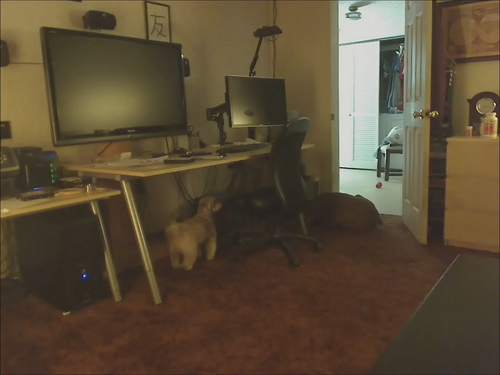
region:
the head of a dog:
[199, 187, 233, 217]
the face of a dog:
[194, 190, 234, 222]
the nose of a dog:
[214, 193, 231, 213]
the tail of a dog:
[163, 220, 187, 248]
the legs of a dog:
[161, 242, 198, 277]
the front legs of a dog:
[194, 225, 241, 267]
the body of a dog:
[168, 187, 220, 267]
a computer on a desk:
[205, 47, 314, 169]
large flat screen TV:
[46, 28, 190, 139]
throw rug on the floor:
[362, 256, 499, 374]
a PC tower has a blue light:
[15, 221, 107, 305]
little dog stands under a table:
[170, 181, 223, 273]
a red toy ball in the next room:
[373, 181, 385, 191]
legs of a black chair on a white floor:
[378, 141, 403, 183]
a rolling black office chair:
[231, 116, 321, 266]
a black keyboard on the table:
[212, 137, 264, 162]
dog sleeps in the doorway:
[310, 188, 385, 237]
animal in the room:
[145, 183, 237, 273]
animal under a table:
[136, 169, 256, 294]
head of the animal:
[191, 188, 231, 227]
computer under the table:
[6, 204, 115, 319]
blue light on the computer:
[63, 254, 100, 296]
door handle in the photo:
[394, 77, 459, 145]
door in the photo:
[317, 2, 491, 239]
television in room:
[17, 28, 230, 184]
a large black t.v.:
[33, 18, 196, 148]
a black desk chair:
[187, 113, 332, 275]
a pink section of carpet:
[0, 199, 433, 371]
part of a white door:
[336, 41, 383, 173]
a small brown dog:
[159, 190, 228, 272]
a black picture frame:
[140, 0, 180, 43]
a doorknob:
[410, 105, 426, 122]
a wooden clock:
[466, 90, 498, 124]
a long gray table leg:
[119, 180, 169, 307]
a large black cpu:
[8, 203, 103, 313]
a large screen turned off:
[38, 20, 190, 145]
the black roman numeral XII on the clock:
[226, 71, 290, 128]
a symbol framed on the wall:
[143, 1, 172, 41]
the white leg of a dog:
[170, 245, 180, 267]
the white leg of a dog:
[180, 241, 197, 268]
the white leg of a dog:
[205, 231, 219, 261]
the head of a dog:
[196, 193, 221, 215]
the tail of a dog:
[162, 219, 183, 238]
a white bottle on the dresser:
[464, 124, 471, 134]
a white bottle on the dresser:
[482, 113, 498, 138]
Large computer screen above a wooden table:
[35, 19, 192, 149]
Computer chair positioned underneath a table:
[238, 113, 325, 268]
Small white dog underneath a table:
[157, 193, 225, 272]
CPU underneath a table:
[10, 208, 112, 317]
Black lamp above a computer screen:
[234, 17, 284, 76]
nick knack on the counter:
[483, 108, 491, 139]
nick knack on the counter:
[465, 88, 496, 133]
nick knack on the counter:
[115, 147, 140, 163]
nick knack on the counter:
[20, 185, 56, 205]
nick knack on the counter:
[56, 182, 82, 199]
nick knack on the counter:
[82, 173, 96, 193]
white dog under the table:
[149, 190, 225, 274]